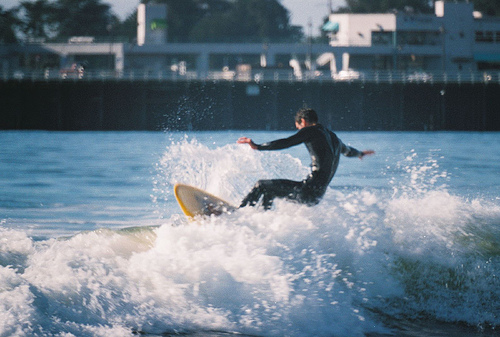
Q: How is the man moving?
A: Surfing.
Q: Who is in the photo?
A: A man.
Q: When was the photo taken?
A: Daytime.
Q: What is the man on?
A: A surfboard.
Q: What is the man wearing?
A: A wetsuit.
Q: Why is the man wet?
A: He's surfing.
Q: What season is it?
A: Summer.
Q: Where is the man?
A: In the ocean.